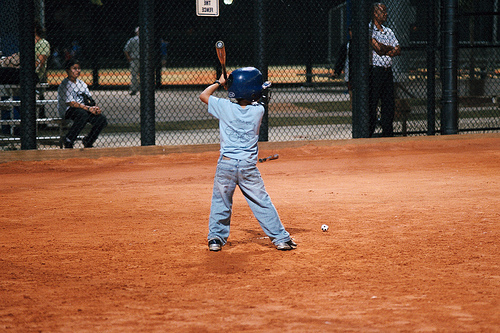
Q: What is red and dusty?
A: The baseball field.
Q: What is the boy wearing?
A: A blue baseball hat.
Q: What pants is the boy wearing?
A: Blue jeans.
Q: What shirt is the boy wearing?
A: A blue t-shirt.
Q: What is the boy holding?
A: A baseball bat.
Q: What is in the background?
A: A black fence.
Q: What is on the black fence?
A: A white sign.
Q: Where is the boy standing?
A: In the red dirt.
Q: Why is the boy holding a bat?
A: Playing baseball.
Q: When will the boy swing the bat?
A: To hit the ball.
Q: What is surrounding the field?
A: A fence.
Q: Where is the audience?
A: Behind the fence.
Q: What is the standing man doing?
A: Watching the boy.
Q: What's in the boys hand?
A: A baseball bat.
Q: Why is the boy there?
A: Batting.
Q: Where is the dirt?
A: On the ground.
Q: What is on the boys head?
A: Helmet.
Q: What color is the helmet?
A: Blue.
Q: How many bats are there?
A: One.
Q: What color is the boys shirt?
A: Blue.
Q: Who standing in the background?
A: A man.